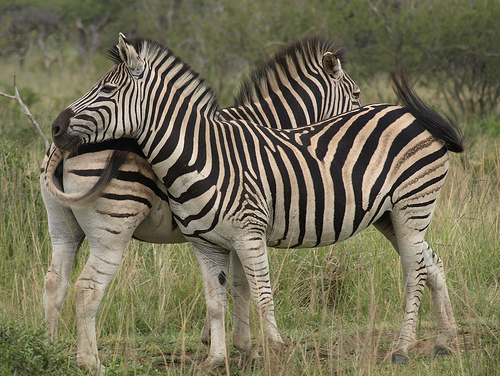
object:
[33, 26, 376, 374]
zebra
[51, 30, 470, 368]
zebra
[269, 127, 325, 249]
black stripes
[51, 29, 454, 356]
fur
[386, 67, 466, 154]
tail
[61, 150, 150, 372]
leg fur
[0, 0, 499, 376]
grass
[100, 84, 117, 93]
eye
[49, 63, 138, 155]
front of face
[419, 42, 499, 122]
bush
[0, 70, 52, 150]
stick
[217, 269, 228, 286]
spot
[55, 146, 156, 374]
leg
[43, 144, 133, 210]
tail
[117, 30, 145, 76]
ear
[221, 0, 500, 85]
plant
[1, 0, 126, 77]
tree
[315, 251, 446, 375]
plant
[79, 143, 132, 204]
black portion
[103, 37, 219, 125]
mane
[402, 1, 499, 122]
tree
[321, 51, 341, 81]
ear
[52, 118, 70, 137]
nose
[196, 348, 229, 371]
hooves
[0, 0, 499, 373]
ground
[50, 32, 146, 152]
head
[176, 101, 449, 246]
body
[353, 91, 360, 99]
eye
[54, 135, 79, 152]
mouth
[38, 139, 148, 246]
rear end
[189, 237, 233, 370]
front leg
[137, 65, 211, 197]
neck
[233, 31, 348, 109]
mane